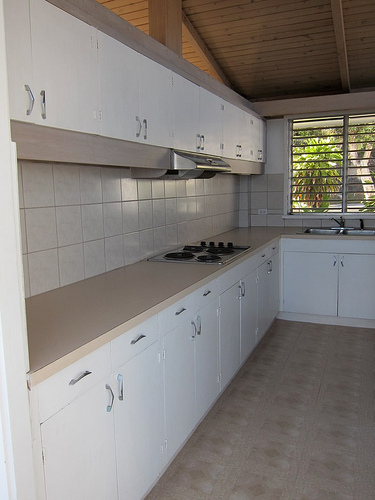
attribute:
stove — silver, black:
[144, 241, 250, 265]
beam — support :
[146, 0, 184, 57]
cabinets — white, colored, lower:
[48, 23, 278, 169]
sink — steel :
[343, 227, 368, 238]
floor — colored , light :
[250, 354, 346, 468]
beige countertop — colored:
[23, 226, 374, 385]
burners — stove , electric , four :
[164, 245, 234, 262]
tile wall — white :
[23, 169, 208, 238]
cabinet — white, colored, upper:
[1, 5, 276, 178]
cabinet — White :
[9, 0, 92, 139]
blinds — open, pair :
[286, 113, 374, 217]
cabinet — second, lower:
[162, 304, 220, 469]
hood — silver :
[168, 151, 233, 183]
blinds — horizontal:
[294, 119, 373, 208]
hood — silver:
[130, 143, 235, 186]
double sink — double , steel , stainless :
[306, 225, 374, 237]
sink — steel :
[304, 218, 374, 243]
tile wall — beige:
[20, 160, 284, 292]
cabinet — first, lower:
[1, 223, 282, 498]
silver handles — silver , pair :
[104, 371, 124, 411]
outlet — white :
[254, 206, 267, 216]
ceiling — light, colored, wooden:
[229, 5, 336, 92]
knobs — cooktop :
[207, 232, 231, 246]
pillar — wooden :
[138, 0, 194, 71]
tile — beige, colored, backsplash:
[21, 163, 57, 210]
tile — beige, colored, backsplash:
[54, 202, 90, 249]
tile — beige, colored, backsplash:
[117, 199, 142, 236]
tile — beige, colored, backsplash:
[176, 194, 188, 219]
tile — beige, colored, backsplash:
[215, 191, 225, 215]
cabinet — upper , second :
[64, 6, 197, 151]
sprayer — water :
[354, 215, 371, 230]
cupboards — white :
[36, 6, 278, 174]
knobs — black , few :
[192, 236, 238, 254]